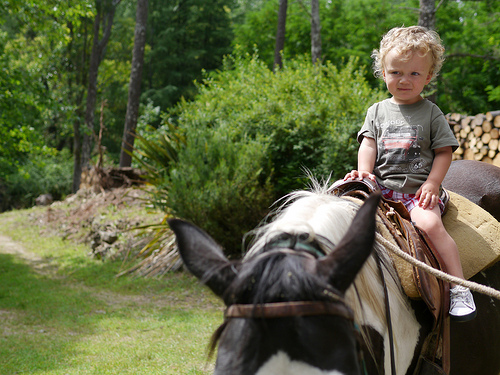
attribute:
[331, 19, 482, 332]
boy — Small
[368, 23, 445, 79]
hair — Blond, curly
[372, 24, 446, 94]
curly hair — blonde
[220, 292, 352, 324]
harness — brown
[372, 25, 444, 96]
hair — Blonde, curly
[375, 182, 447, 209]
shorts — red, white, plaid 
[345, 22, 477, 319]
child — Small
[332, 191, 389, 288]
ear — brown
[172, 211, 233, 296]
ear — brown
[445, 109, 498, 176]
wood — chopped, Stacked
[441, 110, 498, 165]
wood — Stacked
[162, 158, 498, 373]
horse — Black, white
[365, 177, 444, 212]
short — squared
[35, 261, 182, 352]
grass — green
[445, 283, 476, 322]
shoes — white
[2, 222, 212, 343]
path — Dirt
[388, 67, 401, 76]
eye — blue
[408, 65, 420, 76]
eye — blue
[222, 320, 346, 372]
face — brown, white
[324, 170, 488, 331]
saddle — brown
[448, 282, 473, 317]
shoe — white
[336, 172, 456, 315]
saddle — Brown